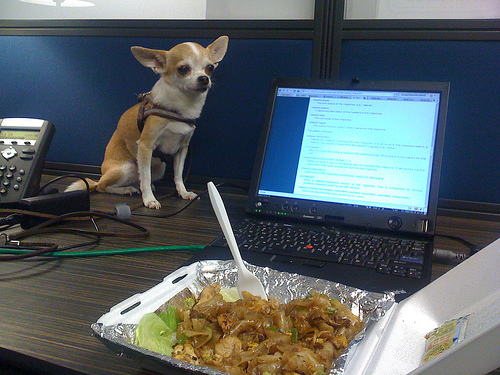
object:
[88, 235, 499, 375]
tray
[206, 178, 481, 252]
cable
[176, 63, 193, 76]
eye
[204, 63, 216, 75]
eye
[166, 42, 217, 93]
face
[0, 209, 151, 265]
wires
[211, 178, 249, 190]
wires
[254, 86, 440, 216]
screen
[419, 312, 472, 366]
packet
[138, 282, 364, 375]
food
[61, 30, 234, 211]
chihuaha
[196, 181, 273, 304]
fork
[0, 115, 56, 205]
phone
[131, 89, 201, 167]
harness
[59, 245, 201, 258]
cable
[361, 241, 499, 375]
styrofoam container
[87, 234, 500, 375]
container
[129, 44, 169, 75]
ear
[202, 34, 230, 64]
ear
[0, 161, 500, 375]
desk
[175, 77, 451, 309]
computer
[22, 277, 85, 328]
brown